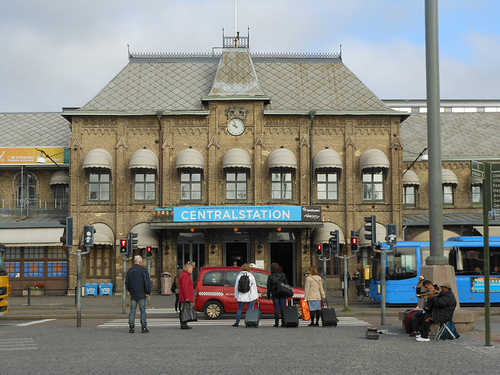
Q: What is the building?
A: A transit station.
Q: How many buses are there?
A: One.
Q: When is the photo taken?
A: Daytime.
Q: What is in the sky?
A: Clouds.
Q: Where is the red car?
A: On the street.